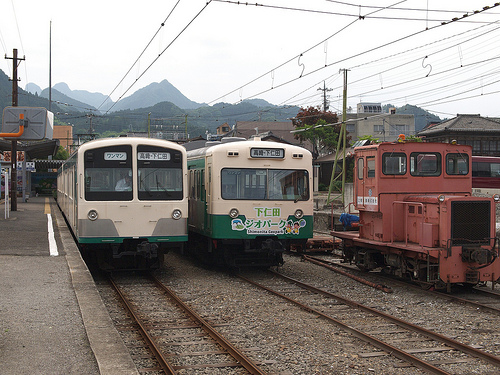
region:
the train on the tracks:
[62, 135, 192, 266]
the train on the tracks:
[180, 120, 324, 265]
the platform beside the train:
[3, 190, 78, 347]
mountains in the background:
[37, 80, 339, 118]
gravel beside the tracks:
[215, 274, 313, 361]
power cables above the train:
[328, 26, 470, 127]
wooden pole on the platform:
[7, 49, 20, 203]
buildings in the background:
[215, 117, 492, 139]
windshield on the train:
[231, 168, 303, 199]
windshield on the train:
[77, 167, 177, 194]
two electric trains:
[49, 134, 314, 270]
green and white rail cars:
[57, 134, 186, 244]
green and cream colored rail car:
[187, 137, 314, 272]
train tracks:
[79, 247, 355, 374]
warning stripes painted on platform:
[42, 197, 60, 256]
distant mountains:
[26, 80, 209, 109]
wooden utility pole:
[4, 46, 26, 213]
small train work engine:
[336, 133, 498, 295]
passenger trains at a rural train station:
[57, 130, 314, 279]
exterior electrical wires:
[95, 0, 497, 130]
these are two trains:
[95, 139, 312, 259]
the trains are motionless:
[99, 139, 308, 252]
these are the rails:
[177, 290, 361, 373]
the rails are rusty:
[324, 294, 383, 334]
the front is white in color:
[123, 213, 165, 236]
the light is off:
[170, 208, 181, 220]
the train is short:
[352, 143, 481, 251]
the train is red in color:
[385, 200, 425, 229]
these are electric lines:
[406, 24, 473, 99]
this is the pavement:
[4, 251, 81, 352]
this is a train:
[64, 132, 176, 271]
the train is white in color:
[108, 206, 136, 221]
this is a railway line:
[119, 281, 211, 372]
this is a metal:
[187, 300, 215, 340]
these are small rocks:
[293, 314, 346, 364]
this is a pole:
[321, 72, 351, 181]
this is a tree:
[303, 111, 339, 155]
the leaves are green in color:
[314, 123, 336, 141]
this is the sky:
[70, 20, 118, 50]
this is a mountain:
[137, 88, 187, 113]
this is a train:
[201, 140, 301, 267]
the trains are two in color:
[79, 132, 307, 261]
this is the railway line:
[302, 281, 358, 348]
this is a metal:
[285, 280, 327, 330]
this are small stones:
[255, 307, 291, 345]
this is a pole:
[334, 70, 353, 161]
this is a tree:
[315, 115, 336, 142]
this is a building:
[356, 107, 411, 131]